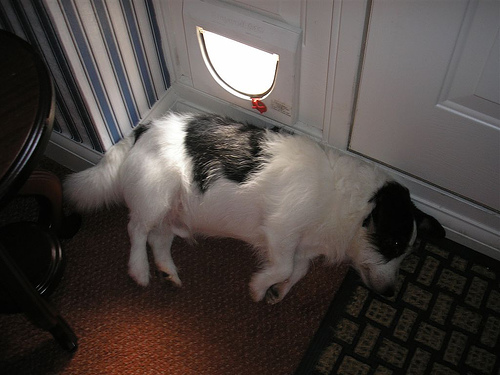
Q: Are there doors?
A: Yes, there is a door.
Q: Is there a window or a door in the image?
A: Yes, there is a door.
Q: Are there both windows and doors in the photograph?
A: No, there is a door but no windows.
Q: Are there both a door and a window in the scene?
A: No, there is a door but no windows.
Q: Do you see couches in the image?
A: No, there are no couches.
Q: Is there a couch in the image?
A: No, there are no couches.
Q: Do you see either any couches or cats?
A: No, there are no couches or cats.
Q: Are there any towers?
A: No, there are no towers.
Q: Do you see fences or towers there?
A: No, there are no towers or fences.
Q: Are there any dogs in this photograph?
A: Yes, there is a dog.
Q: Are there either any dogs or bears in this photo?
A: Yes, there is a dog.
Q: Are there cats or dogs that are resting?
A: Yes, the dog is resting.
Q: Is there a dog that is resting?
A: Yes, there is a dog that is resting.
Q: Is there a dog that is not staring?
A: Yes, there is a dog that is resting.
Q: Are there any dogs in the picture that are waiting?
A: Yes, there is a dog that is waiting.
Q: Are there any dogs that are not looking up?
A: Yes, there is a dog that is waiting.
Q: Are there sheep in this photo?
A: No, there are no sheep.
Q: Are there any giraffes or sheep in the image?
A: No, there are no sheep or giraffes.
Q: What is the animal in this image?
A: The animal is a dog.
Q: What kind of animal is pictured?
A: The animal is a dog.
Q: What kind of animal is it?
A: The animal is a dog.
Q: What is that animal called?
A: That is a dog.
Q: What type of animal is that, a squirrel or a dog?
A: That is a dog.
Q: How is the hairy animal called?
A: The animal is a dog.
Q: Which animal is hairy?
A: The animal is a dog.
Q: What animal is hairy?
A: The animal is a dog.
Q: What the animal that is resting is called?
A: The animal is a dog.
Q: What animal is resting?
A: The animal is a dog.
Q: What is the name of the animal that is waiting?
A: The animal is a dog.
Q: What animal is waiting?
A: The animal is a dog.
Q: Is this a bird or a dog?
A: This is a dog.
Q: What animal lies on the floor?
A: The dog lies on the floor.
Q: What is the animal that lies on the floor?
A: The animal is a dog.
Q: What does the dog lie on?
A: The dog lies on the floor.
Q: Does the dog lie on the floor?
A: Yes, the dog lies on the floor.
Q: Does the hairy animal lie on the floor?
A: Yes, the dog lies on the floor.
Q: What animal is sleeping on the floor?
A: The dog is sleeping on the floor.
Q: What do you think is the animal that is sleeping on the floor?
A: The animal is a dog.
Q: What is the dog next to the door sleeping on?
A: The dog is sleeping on the floor.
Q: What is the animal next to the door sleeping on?
A: The dog is sleeping on the floor.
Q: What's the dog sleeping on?
A: The dog is sleeping on the floor.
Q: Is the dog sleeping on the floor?
A: Yes, the dog is sleeping on the floor.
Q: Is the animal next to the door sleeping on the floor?
A: Yes, the dog is sleeping on the floor.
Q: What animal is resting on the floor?
A: The dog is resting on the floor.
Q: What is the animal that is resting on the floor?
A: The animal is a dog.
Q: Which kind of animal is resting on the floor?
A: The animal is a dog.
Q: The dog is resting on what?
A: The dog is resting on the floor.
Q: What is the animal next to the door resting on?
A: The dog is resting on the floor.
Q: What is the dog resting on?
A: The dog is resting on the floor.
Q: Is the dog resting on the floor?
A: Yes, the dog is resting on the floor.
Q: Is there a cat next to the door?
A: No, there is a dog next to the door.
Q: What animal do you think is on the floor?
A: The animal is a dog.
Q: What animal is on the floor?
A: The animal is a dog.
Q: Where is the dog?
A: The dog is on the floor.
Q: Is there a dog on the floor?
A: Yes, there is a dog on the floor.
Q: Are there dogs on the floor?
A: Yes, there is a dog on the floor.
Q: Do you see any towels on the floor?
A: No, there is a dog on the floor.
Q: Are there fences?
A: No, there are no fences.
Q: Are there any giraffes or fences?
A: No, there are no fences or giraffes.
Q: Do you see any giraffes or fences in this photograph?
A: No, there are no fences or giraffes.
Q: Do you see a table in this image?
A: Yes, there is a table.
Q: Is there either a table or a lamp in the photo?
A: Yes, there is a table.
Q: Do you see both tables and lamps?
A: No, there is a table but no lamps.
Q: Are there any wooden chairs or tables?
A: Yes, there is a wood table.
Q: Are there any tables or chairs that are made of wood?
A: Yes, the table is made of wood.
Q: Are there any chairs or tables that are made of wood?
A: Yes, the table is made of wood.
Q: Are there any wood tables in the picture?
A: Yes, there is a wood table.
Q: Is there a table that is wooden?
A: Yes, there is a table that is wooden.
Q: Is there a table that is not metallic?
A: Yes, there is a wooden table.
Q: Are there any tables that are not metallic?
A: Yes, there is a wooden table.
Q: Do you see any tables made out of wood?
A: Yes, there is a table that is made of wood.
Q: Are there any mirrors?
A: No, there are no mirrors.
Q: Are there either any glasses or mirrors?
A: No, there are no mirrors or glasses.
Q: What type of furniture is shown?
A: The furniture is a table.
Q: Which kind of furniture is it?
A: The piece of furniture is a table.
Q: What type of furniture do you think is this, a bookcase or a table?
A: This is a table.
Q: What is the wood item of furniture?
A: The piece of furniture is a table.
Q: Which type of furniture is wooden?
A: The furniture is a table.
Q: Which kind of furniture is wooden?
A: The furniture is a table.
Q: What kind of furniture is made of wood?
A: The furniture is a table.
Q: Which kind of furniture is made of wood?
A: The furniture is a table.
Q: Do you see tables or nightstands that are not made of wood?
A: No, there is a table but it is made of wood.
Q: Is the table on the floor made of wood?
A: Yes, the table is made of wood.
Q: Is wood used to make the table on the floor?
A: Yes, the table is made of wood.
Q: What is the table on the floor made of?
A: The table is made of wood.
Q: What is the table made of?
A: The table is made of wood.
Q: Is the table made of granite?
A: No, the table is made of wood.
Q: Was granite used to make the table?
A: No, the table is made of wood.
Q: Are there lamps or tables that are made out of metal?
A: No, there is a table but it is made of wood.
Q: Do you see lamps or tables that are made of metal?
A: No, there is a table but it is made of wood.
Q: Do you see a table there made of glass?
A: No, there is a table but it is made of wood.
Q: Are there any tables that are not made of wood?
A: No, there is a table but it is made of wood.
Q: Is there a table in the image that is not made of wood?
A: No, there is a table but it is made of wood.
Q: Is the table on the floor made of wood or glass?
A: The table is made of wood.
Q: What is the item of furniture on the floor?
A: The piece of furniture is a table.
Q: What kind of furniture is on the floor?
A: The piece of furniture is a table.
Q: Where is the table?
A: The table is on the floor.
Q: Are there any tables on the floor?
A: Yes, there is a table on the floor.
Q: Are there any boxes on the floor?
A: No, there is a table on the floor.